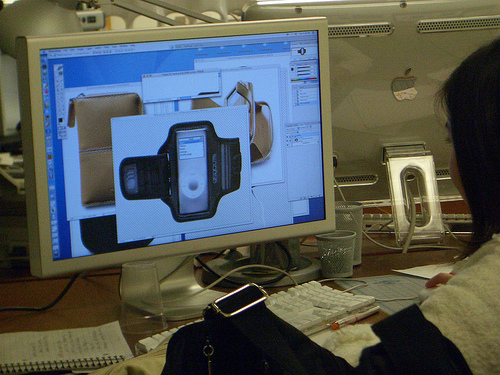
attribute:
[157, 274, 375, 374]
purse — black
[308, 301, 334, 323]
key — white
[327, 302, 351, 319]
key — white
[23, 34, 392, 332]
computer — on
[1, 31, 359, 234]
monitor — on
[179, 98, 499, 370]
lady — Asian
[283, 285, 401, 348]
pen — orange, white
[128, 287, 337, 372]
purse — black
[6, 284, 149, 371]
notebook — spiral-bound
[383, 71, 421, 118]
logo — shiny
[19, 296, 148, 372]
notebook — white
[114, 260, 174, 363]
cup — clear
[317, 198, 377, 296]
cup — small, metal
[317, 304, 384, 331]
pen — orange, white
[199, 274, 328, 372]
bag — black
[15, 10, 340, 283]
screen — bluish in color, computer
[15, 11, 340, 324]
monitor — grey in color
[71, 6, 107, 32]
plug — silver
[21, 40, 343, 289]
frame — metal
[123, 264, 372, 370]
keyboard — computer , right side 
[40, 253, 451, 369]
desk — clear cup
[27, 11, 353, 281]
computer — apple logo 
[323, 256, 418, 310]
mousepad — gray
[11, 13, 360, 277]
monitor — large